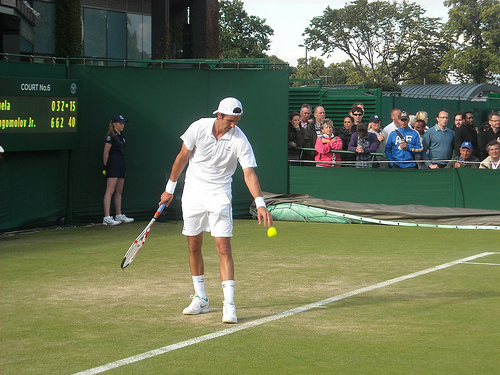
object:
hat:
[209, 96, 243, 116]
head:
[211, 98, 243, 135]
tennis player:
[158, 96, 274, 324]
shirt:
[179, 116, 262, 199]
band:
[254, 196, 269, 210]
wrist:
[251, 192, 266, 209]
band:
[165, 179, 177, 193]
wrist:
[163, 178, 178, 193]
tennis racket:
[117, 204, 171, 270]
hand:
[158, 192, 175, 206]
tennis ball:
[267, 225, 280, 239]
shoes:
[222, 298, 237, 325]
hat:
[111, 115, 129, 123]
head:
[113, 116, 127, 134]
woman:
[97, 112, 135, 226]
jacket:
[382, 127, 423, 164]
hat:
[398, 111, 409, 122]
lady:
[312, 119, 343, 164]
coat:
[314, 136, 344, 165]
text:
[1, 100, 77, 128]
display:
[2, 77, 79, 150]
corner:
[55, 72, 90, 228]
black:
[110, 135, 126, 178]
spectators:
[385, 114, 425, 168]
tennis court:
[4, 213, 495, 374]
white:
[191, 139, 229, 211]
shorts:
[181, 204, 234, 239]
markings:
[55, 248, 499, 375]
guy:
[426, 109, 455, 170]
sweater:
[424, 126, 455, 167]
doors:
[81, 6, 108, 65]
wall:
[4, 59, 285, 224]